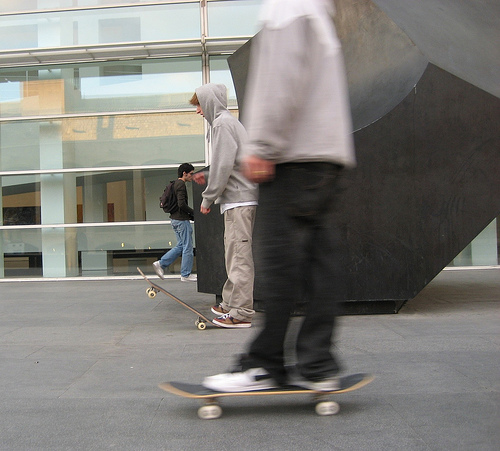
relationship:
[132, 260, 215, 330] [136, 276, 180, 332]
skateboard standing up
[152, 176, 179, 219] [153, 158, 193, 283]
backpack on man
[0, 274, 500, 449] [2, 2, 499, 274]
sidewalk in front of building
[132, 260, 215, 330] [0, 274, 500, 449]
skateboard on sidewalk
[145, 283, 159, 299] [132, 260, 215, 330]
wheels of skateboard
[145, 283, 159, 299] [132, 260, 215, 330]
wheels on skateboard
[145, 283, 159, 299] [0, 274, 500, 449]
wheels on sidewalk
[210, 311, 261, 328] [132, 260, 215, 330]
foot on skateboard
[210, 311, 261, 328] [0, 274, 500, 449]
foot on sidewalk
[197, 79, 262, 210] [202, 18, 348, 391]
sweatshirt on person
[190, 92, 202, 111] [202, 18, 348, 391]
hair of person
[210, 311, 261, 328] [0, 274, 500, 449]
foot on ground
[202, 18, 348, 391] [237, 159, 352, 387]
person wearing pants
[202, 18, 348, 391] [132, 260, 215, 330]
person on skateboard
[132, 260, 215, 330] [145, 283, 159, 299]
skateboard has wheels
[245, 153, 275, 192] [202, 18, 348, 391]
hand of person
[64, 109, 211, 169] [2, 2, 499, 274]
window of building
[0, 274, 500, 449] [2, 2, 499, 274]
sidewalk by building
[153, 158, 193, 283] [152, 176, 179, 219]
man has backpack